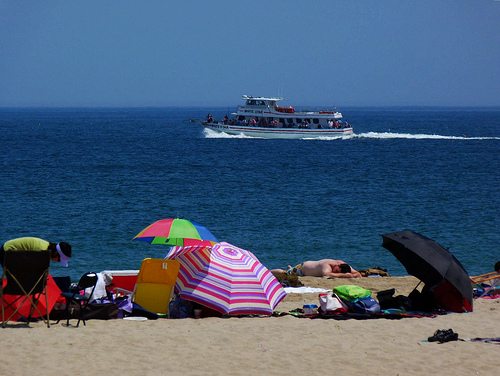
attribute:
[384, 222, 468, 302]
umbrella — black, multicolored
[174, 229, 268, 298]
umbrella — striped, red, multicolored, colorful, blue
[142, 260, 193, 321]
chair — yellow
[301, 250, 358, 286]
man — laying, bare, sleeping, pale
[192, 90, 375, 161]
boat — white, leaving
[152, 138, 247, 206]
ocean — calm, blue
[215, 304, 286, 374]
beach — sandy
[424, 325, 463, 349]
shoes — black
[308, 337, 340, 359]
sand — tan, brown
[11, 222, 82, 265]
person — bending, leaning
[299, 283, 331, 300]
towel — green